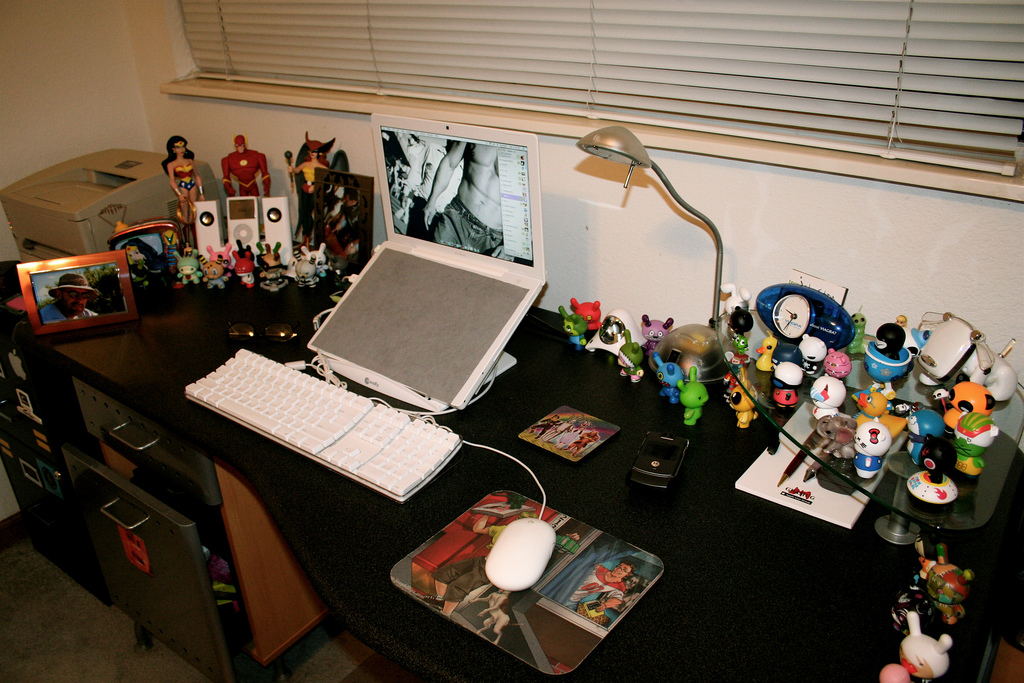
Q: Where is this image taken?
A: In home office.